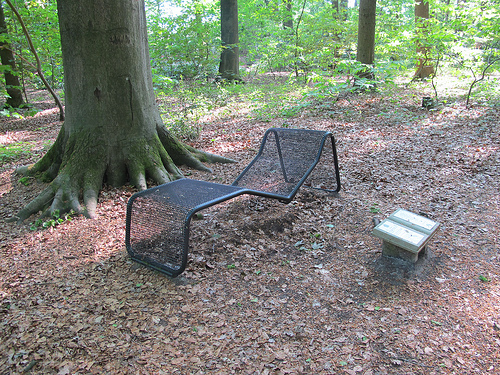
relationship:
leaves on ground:
[47, 236, 117, 298] [10, 79, 499, 375]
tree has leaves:
[290, 9, 358, 88] [314, 18, 334, 34]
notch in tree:
[93, 87, 100, 98] [290, 9, 358, 88]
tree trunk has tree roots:
[56, 5, 173, 137] [15, 130, 234, 216]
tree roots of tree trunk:
[15, 130, 234, 216] [56, 5, 173, 137]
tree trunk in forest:
[56, 5, 173, 137] [3, 2, 499, 375]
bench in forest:
[125, 126, 343, 277] [3, 2, 499, 375]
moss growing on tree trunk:
[74, 120, 167, 170] [56, 5, 173, 137]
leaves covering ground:
[47, 236, 117, 298] [10, 79, 499, 375]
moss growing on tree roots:
[74, 120, 167, 170] [15, 130, 234, 216]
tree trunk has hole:
[56, 5, 173, 137] [71, 115, 81, 122]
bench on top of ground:
[125, 126, 343, 277] [10, 79, 499, 375]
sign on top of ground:
[422, 97, 445, 118] [10, 79, 499, 375]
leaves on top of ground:
[47, 236, 117, 298] [10, 79, 499, 375]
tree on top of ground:
[290, 9, 358, 88] [10, 79, 499, 375]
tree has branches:
[290, 9, 358, 88] [268, 35, 310, 68]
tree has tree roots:
[290, 9, 358, 88] [15, 130, 234, 216]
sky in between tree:
[281, 0, 325, 22] [290, 9, 358, 88]